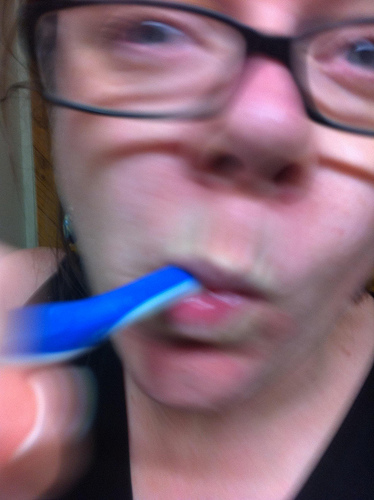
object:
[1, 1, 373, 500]
person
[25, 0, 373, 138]
glasses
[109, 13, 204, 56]
eyes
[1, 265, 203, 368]
toothbrush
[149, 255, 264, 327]
mouth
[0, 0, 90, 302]
hair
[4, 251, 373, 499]
top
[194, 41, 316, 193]
nose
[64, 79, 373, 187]
shadow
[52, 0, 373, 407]
face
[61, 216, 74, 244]
earring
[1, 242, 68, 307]
shoulder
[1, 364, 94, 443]
fingers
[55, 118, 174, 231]
cheek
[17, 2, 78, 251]
doorway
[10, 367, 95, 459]
nail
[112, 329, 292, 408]
chin